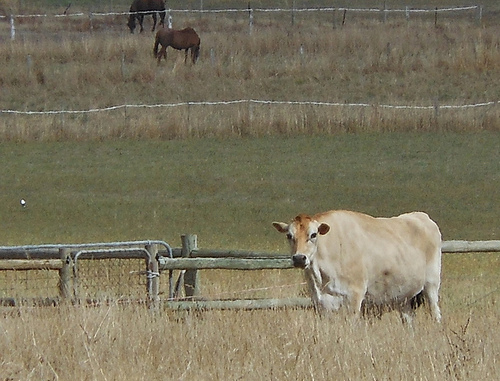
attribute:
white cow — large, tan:
[262, 206, 457, 328]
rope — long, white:
[0, 93, 500, 114]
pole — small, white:
[247, 0, 252, 39]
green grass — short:
[3, 130, 498, 207]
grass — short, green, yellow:
[177, 138, 219, 190]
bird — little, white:
[8, 187, 33, 210]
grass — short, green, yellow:
[91, 152, 281, 207]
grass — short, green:
[128, 150, 245, 232]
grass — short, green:
[65, 154, 317, 268]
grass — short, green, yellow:
[0, 127, 498, 251]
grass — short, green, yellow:
[1, 139, 498, 269]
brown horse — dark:
[151, 27, 202, 69]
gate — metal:
[73, 241, 160, 318]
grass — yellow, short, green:
[14, 211, 261, 238]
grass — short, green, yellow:
[15, 139, 383, 220]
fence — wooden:
[184, 220, 245, 312]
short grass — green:
[189, 177, 236, 209]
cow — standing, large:
[271, 210, 446, 332]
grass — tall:
[0, 258, 499, 380]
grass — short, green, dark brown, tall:
[9, 8, 494, 379]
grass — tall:
[179, 305, 351, 377]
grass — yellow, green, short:
[53, 140, 184, 187]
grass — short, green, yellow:
[3, 127, 498, 292]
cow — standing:
[277, 209, 472, 340]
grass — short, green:
[43, 142, 130, 191]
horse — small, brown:
[126, 13, 226, 64]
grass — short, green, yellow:
[3, 131, 483, 246]